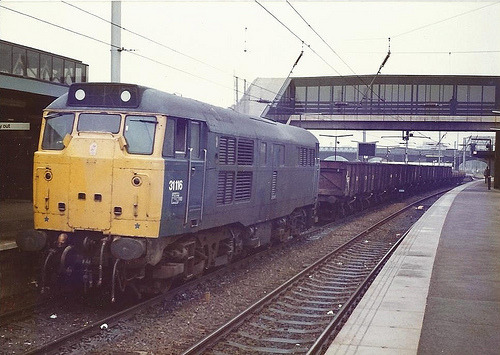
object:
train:
[17, 82, 466, 310]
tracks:
[1, 174, 485, 354]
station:
[0, 1, 499, 352]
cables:
[281, 0, 499, 166]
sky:
[0, 0, 499, 110]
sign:
[0, 121, 32, 131]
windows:
[0, 38, 13, 79]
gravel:
[0, 173, 499, 354]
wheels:
[270, 216, 295, 248]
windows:
[118, 110, 158, 160]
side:
[155, 97, 468, 301]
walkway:
[322, 177, 498, 355]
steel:
[42, 173, 99, 228]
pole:
[110, 0, 122, 83]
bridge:
[227, 75, 498, 134]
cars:
[316, 156, 469, 226]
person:
[483, 167, 491, 185]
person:
[447, 95, 457, 114]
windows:
[291, 85, 306, 115]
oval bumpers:
[15, 223, 49, 256]